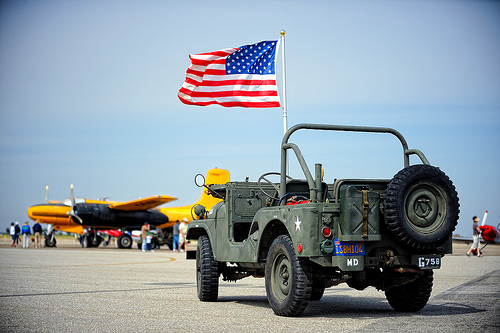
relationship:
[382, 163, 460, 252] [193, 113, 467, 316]
tire on back of jeep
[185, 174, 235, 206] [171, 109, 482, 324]
mirror on side of jeep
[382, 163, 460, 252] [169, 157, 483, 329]
tire inside jeep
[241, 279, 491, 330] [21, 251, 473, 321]
shadow on ground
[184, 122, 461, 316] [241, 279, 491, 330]
army jeep has shadow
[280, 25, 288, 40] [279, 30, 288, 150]
ball on top of pole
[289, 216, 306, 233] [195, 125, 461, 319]
star on army jeep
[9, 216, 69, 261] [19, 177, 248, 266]
people stand near airplane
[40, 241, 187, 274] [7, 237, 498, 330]
line painted on runway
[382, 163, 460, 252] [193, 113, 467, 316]
tire attached to jeep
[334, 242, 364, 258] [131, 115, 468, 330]
license plate attached to truck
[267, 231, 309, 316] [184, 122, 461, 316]
tire part of army jeep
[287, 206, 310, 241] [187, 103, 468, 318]
design part of truck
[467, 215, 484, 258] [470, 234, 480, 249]
person wears pants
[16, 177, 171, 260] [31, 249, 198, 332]
airplane resting on runway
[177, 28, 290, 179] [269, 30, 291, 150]
flag on flag pole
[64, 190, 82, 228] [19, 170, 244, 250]
propeller on plane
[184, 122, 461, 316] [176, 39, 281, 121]
army jeep front of flag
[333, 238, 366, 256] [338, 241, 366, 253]
license plate has lettering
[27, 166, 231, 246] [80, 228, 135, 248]
airplane has landing gear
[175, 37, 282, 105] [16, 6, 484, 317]
flag flying in wind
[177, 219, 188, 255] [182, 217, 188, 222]
man with hat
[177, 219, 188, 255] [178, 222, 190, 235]
man with shirt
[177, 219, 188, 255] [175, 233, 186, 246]
man with pants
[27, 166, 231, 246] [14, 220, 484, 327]
airplane on ground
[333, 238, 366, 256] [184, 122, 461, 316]
license plate on army jeep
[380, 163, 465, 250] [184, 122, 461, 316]
tire on army jeep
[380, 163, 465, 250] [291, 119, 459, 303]
tire on back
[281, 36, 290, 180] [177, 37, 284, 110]
flag pole holding up flag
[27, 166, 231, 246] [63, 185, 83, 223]
airplane has propellar